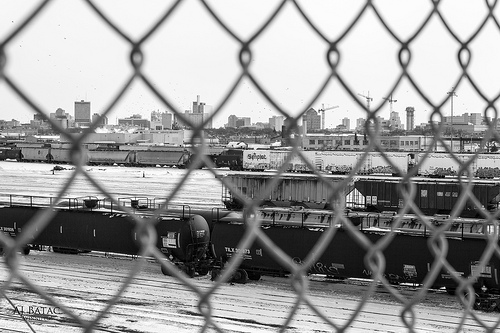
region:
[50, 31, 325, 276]
a cage fence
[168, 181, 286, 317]
a cage fence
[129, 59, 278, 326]
a cage fence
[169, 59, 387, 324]
a cage fence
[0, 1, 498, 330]
Scene is black and white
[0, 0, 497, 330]
fence is chain link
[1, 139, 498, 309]
railroad cars carry frieght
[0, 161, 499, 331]
tracks are covered in snow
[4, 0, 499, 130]
the sky is clear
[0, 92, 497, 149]
the skyline is city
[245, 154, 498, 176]
train cars have graffiti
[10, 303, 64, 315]
watermark in bottom left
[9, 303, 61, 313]
watermark says aj batac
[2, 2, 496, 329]
fence is made of metal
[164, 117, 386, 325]
the fence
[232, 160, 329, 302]
the fence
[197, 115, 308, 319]
the fence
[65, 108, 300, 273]
a chain fence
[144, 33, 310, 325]
a chain fence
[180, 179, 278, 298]
a chain fence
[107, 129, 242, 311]
a chain fence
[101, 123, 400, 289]
trains behind fence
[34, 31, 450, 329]
chain link fence in front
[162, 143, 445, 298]
lines of train cars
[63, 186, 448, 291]
black circular train cars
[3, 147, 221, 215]
numerous trains on tracks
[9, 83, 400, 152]
city with buildings in distance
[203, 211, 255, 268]
white letters and numbers on circular cars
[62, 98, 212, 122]
skyscrapers in distance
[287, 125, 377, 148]
building with square windows in distance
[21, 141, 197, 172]
long train cars